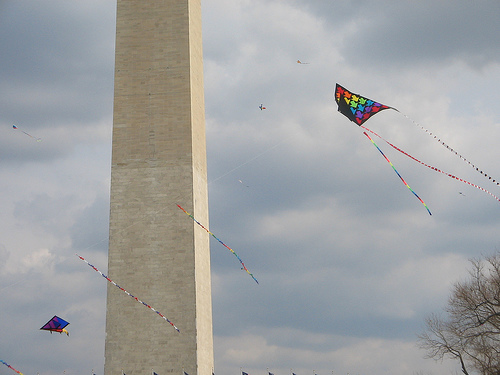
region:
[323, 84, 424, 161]
kite in the sky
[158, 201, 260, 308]
tail of the kite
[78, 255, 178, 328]
tail of the kite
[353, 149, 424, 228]
tail of the kite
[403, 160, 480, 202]
tail of the kite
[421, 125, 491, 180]
tail of the kite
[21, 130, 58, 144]
tail of the kite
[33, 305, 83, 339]
kite in the sky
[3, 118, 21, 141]
kite in the sky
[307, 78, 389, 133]
kite in the sky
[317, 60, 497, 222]
This is a rainbow kite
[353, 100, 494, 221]
This kite has streamers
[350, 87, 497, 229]
Three long streamers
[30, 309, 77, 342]
Small multicolored kite in sky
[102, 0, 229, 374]
This is the Washington monument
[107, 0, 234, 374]
Washington monument is tall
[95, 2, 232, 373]
This is the Washington monument is Washington, D.C.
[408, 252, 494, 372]
Dry and dead tree branches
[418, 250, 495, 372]
This is a tree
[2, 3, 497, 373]
Very cloudy skies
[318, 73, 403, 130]
kite in sky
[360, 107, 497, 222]
tails on end of kite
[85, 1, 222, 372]
grey stone tower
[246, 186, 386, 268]
white misty cloud in light blue sky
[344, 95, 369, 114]
multicolored arrows on kite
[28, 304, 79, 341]
purple, blue, red and yellow kite in sky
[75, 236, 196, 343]
red , blue and white kite tail in sky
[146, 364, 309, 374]
black edges of object in foreground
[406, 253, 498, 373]
leafless brown tree branches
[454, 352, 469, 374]
brown tree trunk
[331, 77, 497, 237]
Rainbow colored kite flying.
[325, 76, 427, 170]
Kite has colored arrows decorating it.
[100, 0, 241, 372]
Large tower made of brick.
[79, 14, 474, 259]
Kites being flown by tower.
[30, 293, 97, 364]
Red, blue and yellow kite.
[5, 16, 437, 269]
Cloudy day while kite flying.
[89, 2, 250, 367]
Cream colored tower with smooth sides.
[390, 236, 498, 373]
Tree with no leaves near tower.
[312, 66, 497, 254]
Kite has long colored tails.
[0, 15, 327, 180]
Kites flying high in the sky.